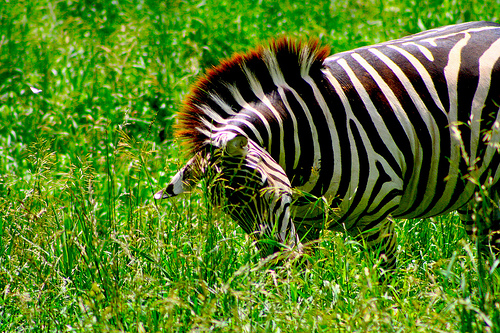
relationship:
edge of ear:
[153, 154, 198, 194] [152, 151, 204, 200]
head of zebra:
[153, 71, 309, 270] [152, 21, 498, 292]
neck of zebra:
[234, 75, 319, 187] [152, 21, 498, 292]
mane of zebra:
[171, 31, 329, 147] [152, 21, 498, 292]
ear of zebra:
[152, 151, 204, 200] [152, 21, 498, 292]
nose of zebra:
[235, 210, 304, 277] [152, 21, 498, 292]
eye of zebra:
[258, 179, 268, 192] [152, 21, 498, 292]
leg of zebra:
[356, 215, 396, 291] [152, 21, 498, 292]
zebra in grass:
[152, 21, 498, 292] [2, 0, 500, 332]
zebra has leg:
[152, 21, 498, 292] [356, 215, 396, 291]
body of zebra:
[323, 16, 498, 219] [152, 21, 498, 292]